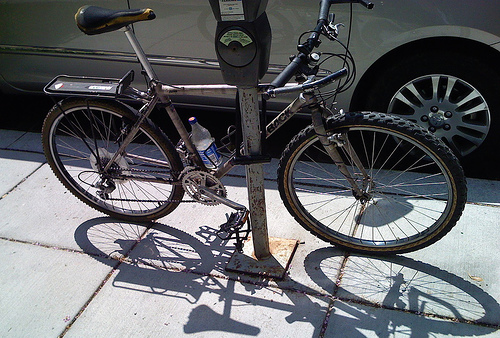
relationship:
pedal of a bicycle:
[224, 208, 249, 234] [35, 0, 470, 259]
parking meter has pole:
[204, 0, 274, 90] [226, 85, 301, 281]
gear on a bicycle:
[180, 168, 227, 208] [35, 0, 470, 259]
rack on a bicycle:
[43, 69, 144, 101] [35, 0, 470, 259]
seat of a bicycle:
[73, 5, 165, 34] [35, 0, 470, 259]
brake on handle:
[301, 72, 316, 98] [261, 1, 377, 95]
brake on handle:
[322, 11, 346, 42] [261, 1, 377, 95]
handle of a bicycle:
[261, 1, 377, 95] [35, 0, 470, 259]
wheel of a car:
[353, 47, 499, 176] [1, 0, 499, 176]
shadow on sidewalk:
[1, 127, 499, 211] [1, 127, 498, 337]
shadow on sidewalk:
[73, 214, 499, 337] [1, 127, 498, 337]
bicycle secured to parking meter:
[35, 0, 470, 259] [204, 0, 274, 90]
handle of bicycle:
[261, 1, 377, 95] [35, 0, 470, 259]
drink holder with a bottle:
[182, 137, 226, 175] [185, 117, 221, 169]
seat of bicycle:
[73, 5, 165, 34] [35, 0, 470, 259]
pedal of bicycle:
[224, 208, 249, 234] [35, 0, 470, 259]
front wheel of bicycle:
[275, 110, 466, 258] [35, 0, 470, 259]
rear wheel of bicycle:
[41, 92, 191, 223] [35, 0, 470, 259]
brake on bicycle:
[301, 72, 316, 98] [35, 0, 470, 259]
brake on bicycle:
[322, 11, 346, 42] [35, 0, 470, 259]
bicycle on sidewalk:
[35, 0, 470, 259] [1, 127, 498, 337]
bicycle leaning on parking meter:
[35, 0, 470, 259] [204, 0, 274, 90]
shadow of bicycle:
[73, 214, 499, 337] [35, 0, 470, 259]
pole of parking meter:
[226, 85, 301, 281] [204, 0, 274, 90]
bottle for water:
[185, 117, 221, 169] [199, 144, 221, 171]